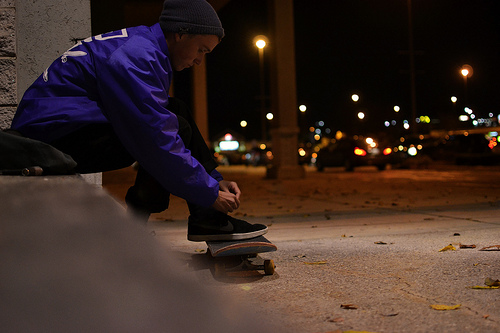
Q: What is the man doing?
A: Tying his shoe.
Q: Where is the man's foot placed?
A: On a skateboard.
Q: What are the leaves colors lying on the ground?
A: Brown and yellow.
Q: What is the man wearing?
A: A purple and white jacket.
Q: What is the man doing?
A: Tying his shoes.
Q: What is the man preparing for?
A: Skateboarding.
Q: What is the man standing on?
A: A skateboard.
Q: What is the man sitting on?
A: A bench.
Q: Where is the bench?
A: Below the man.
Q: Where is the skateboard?
A: Below the man.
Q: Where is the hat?
A: On the man's head.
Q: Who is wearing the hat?
A: The man.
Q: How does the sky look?
A: Black.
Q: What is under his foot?
A: A skateboard.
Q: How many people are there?
A: One.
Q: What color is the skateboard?
A: Black.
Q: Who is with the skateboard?
A: A boy.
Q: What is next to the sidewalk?
A: Cars.